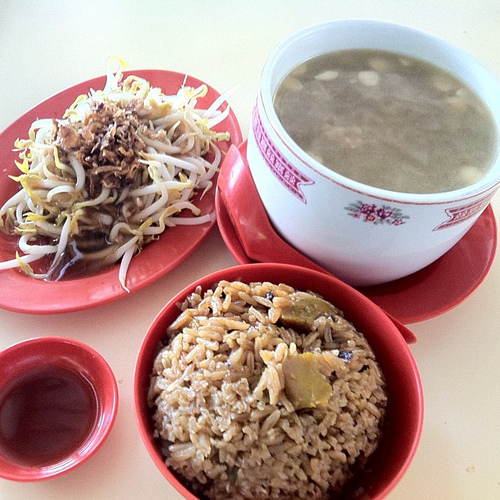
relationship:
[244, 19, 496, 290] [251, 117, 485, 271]
cup has designs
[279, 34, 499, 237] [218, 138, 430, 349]
soup has spoon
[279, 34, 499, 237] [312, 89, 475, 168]
miso soup has mushrooms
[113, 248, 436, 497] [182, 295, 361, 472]
bowl has rice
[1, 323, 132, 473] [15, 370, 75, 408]
bowl has sauce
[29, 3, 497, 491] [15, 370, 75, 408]
food has sauce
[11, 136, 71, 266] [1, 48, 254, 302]
noodles on top of a plate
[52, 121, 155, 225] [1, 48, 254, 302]
vegetables on top of a plate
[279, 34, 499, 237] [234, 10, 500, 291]
soup inside of bowl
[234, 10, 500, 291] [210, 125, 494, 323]
bowl on top of dish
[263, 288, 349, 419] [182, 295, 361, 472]
vegetables sitting on top of rice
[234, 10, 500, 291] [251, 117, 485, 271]
bowl has designs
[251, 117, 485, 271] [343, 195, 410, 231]
designs have designs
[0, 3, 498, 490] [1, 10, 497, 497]
food sitting on top of table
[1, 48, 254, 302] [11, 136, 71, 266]
plate has noodles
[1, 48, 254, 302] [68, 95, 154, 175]
plate has meat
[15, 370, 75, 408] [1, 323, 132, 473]
sauce inside of a bowl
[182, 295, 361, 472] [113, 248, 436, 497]
rice inside of bowl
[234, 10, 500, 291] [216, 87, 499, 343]
bowl sitting inside of bowl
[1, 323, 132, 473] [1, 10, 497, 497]
bowl on top of table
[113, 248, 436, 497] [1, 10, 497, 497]
bowl on top of table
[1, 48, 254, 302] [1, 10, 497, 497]
plate on top of table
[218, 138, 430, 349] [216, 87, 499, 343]
spoon sitting in bowl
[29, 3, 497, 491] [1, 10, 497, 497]
food on top of table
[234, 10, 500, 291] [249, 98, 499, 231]
bowl has markings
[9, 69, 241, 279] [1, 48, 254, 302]
sprouts are on top of plate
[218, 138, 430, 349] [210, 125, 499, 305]
spoon on top of dish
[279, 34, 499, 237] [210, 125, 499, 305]
soup on top of dish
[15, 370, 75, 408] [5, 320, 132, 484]
sauce inside of dish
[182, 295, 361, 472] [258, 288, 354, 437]
rice has meat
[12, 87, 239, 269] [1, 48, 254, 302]
bean sprouts on top of plate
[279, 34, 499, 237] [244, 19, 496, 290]
soup inside of cup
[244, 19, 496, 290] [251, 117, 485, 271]
cup has design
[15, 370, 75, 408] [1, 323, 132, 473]
sauce inside of side dish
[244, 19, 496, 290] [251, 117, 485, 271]
cup has marking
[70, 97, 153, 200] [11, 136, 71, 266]
toppings on top of noodles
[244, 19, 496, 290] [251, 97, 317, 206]
cup has charcters